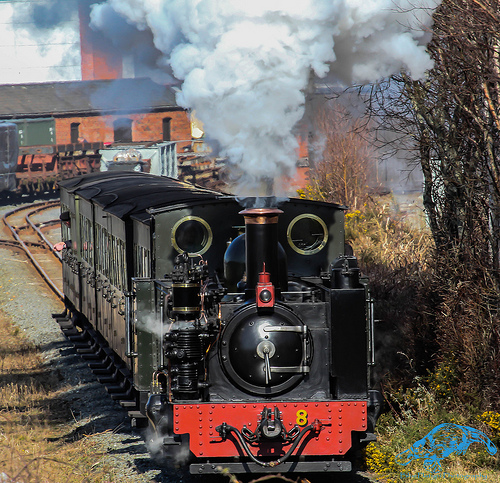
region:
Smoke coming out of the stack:
[165, 28, 342, 225]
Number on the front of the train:
[286, 406, 311, 428]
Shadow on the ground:
[35, 309, 117, 479]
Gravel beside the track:
[82, 384, 116, 439]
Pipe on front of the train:
[211, 422, 329, 479]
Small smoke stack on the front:
[115, 263, 208, 409]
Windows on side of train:
[80, 212, 142, 297]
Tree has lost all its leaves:
[400, 16, 496, 151]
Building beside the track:
[14, 62, 219, 189]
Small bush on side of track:
[291, 66, 408, 232]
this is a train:
[29, 165, 399, 481]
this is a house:
[1, 77, 218, 223]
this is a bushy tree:
[317, 93, 404, 293]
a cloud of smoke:
[176, 64, 268, 175]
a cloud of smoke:
[243, 51, 290, 151]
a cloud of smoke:
[149, 36, 255, 122]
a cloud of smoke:
[222, 4, 317, 84]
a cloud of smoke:
[379, 28, 436, 98]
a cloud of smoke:
[153, 47, 223, 98]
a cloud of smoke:
[221, 9, 283, 120]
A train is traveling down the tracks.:
[0, 2, 496, 480]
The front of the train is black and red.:
[160, 206, 375, 476]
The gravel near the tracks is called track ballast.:
[0, 265, 46, 320]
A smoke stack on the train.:
[240, 190, 280, 300]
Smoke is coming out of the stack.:
[118, 0, 321, 200]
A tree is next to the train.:
[385, 0, 496, 400]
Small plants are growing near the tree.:
[365, 372, 498, 477]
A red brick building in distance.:
[0, 77, 191, 162]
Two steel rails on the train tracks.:
[5, 205, 60, 280]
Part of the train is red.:
[171, 403, 371, 460]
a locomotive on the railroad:
[45, 149, 385, 480]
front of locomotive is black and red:
[151, 213, 378, 463]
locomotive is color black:
[46, 158, 382, 474]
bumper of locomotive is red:
[151, 395, 372, 460]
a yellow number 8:
[281, 402, 318, 433]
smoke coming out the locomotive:
[114, 3, 398, 214]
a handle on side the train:
[117, 279, 145, 366]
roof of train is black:
[45, 156, 242, 223]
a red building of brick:
[0, 66, 202, 181]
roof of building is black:
[5, 73, 195, 124]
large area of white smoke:
[192, 38, 322, 165]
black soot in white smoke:
[67, 18, 157, 87]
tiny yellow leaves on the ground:
[368, 443, 404, 463]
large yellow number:
[291, 405, 319, 427]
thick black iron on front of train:
[210, 419, 335, 465]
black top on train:
[48, 156, 229, 217]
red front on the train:
[162, 399, 368, 449]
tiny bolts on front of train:
[177, 403, 215, 419]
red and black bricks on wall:
[135, 115, 155, 134]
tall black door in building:
[102, 116, 139, 145]